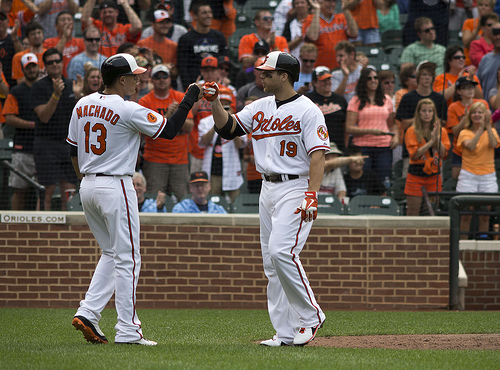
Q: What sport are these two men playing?
A: Baseball.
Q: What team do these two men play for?
A: The Orioles.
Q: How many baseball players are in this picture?
A: 2.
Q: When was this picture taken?
A: Daytime.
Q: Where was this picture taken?
A: The baseball field.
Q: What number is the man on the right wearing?
A: 19.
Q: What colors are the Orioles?
A: Orange, black and white.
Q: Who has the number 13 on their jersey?
A: Machado.